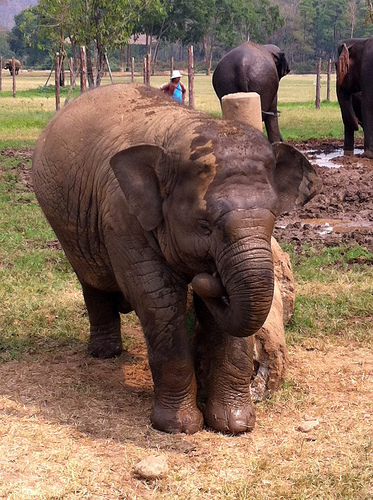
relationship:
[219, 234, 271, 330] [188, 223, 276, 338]
wrinkles on elephant trunk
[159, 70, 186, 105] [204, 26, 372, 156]
man watching elephants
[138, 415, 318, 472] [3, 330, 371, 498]
rocks on ground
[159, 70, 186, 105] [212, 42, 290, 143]
man observing animal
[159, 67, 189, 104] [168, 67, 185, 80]
man wearing hat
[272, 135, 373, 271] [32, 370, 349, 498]
mud in ground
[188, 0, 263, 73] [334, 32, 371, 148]
tree in a field of elephant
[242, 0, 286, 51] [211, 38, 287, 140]
tree in a field of elephant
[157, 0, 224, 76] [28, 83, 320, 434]
tree in a field of elephant